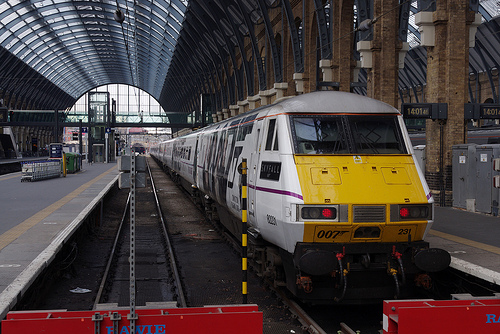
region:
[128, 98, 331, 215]
The train station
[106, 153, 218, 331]
Tracks in the station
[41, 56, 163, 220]
The train terminal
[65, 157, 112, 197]
The platform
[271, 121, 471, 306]
The train has a yellow front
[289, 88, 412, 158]
The front windows of the train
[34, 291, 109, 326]
Bumpers for the trains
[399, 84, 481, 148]
A sign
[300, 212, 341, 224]
Lights on the train in the station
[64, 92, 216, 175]
Its daylight outside the station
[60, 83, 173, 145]
The circular opening at the end of the station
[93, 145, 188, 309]
The track with no train on it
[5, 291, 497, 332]
The red bumpers in front of the train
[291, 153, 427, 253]
The yellow part of the train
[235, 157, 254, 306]
The black and yellow pole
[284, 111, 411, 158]
The windshield on the front of the train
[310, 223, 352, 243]
007 on the front of the train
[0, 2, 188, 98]
The lights in the middle of the ceiling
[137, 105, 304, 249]
The white side of the train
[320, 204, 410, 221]
The red lights on the front of the train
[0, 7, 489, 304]
train is at platform in a trainstation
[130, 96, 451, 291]
a yellow and white train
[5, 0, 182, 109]
arched roof of train station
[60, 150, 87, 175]
garbage bins on train platform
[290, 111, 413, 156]
windows of a train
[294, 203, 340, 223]
head light of a train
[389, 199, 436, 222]
headlight of train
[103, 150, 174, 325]
empty rail tracks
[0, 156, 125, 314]
train platform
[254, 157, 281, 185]
advertising on the side of a train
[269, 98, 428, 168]
two square wind shields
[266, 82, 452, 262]
a train with yellow front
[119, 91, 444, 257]
a long white train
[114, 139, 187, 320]
a straight train track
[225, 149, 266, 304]
a yellow and black pole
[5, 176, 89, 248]
yellow stripe on the walkway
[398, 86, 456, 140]
a train station sign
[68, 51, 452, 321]
a train in station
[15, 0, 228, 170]
a high domed ceiling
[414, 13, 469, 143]
a brick pillar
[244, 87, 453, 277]
the front of the train is yellow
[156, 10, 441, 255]
this appears to be a metro type train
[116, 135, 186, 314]
the train track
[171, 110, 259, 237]
the train has writing on the side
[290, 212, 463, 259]
the train has 007 on the front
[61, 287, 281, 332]
there are big red things in the foreground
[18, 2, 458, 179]
the train is running through a tunnel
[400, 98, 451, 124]
the sign has 1401 on it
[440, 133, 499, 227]
the electrical boxes are grey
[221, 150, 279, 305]
the post is yellow and black